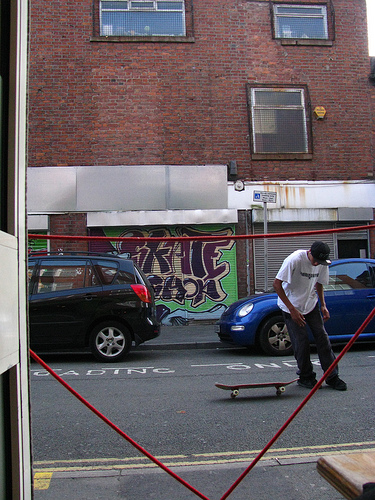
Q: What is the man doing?
A: Skateboarding.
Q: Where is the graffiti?
A: On the brick building.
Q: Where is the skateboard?
A: On the street.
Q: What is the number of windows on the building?
A: 3.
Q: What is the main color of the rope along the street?
A: Red.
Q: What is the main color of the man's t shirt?
A: White.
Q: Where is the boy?
A: In the street.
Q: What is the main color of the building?
A: Red.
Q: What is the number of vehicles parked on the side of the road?
A: 2.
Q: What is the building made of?
A: Brick.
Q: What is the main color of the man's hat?
A: Black.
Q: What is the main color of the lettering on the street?
A: White.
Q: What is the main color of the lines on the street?
A: Yellow.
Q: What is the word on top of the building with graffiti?
A: Skate.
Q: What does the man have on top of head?
A: Cap.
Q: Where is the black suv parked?
A: In front of a building.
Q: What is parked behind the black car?
A: Blue car.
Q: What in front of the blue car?
A: Black suv.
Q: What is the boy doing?
A: Standing in the road.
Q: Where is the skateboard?
A: In the road.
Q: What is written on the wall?
A: Graffiti.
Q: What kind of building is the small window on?
A: Brick building.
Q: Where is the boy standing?
A: Road.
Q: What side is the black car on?
A: Left.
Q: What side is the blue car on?
A: Right.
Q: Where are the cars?
A: Behind skateboarder.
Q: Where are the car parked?
A: Along curb.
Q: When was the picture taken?
A: Daytime.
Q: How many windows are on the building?
A: 3.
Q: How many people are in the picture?
A: 1.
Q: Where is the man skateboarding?
A: On street.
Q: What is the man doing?
A: Skateboarding.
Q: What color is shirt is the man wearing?
A: White.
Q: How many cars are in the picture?
A: 2.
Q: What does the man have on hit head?
A: Hat.